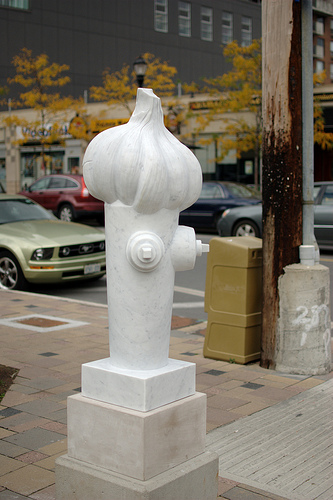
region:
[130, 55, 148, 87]
a black lamp post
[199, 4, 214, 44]
a window on a building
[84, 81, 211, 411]
a statue of a fire hydrant with a garlic head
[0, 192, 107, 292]
a Ford Mustang parked alongside the road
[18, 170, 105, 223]
a red car parked alongside the road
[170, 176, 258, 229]
a navy car parked alongside the road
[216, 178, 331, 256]
a grey car driving on a road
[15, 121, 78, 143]
a sign above a store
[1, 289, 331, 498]
a sidewalk next to a road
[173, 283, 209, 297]
a white stripe in a road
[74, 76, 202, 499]
white decorative statue placed on the sidewalk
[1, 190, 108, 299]
green Ford mustang parked in the street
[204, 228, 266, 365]
tan colored newspaper holder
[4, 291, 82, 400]
multi-colored brick sidewalk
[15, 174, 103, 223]
Four door maroon car parked in the street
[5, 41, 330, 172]
skinny trees with minimal yellow leaves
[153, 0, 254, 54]
row of windows on a multi-story building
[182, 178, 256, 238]
Navy blue vehicle parked in the street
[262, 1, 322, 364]
tall multi-hued brown telephone pole next to the sidewalk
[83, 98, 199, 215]
top shaped like onion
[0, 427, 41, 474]
bricks on the ground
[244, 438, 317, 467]
wood on the ground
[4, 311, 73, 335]
square on the ground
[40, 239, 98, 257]
front of mustang car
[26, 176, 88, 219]
side of the suv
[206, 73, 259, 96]
leaves of the tree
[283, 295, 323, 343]
graffiti on the pole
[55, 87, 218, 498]
White fire hydrant with garlic shaped top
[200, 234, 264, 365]
Golden mail vending machine in the background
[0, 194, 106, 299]
Golden Ford Mustang in the background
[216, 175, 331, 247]
Grey car driving by in the background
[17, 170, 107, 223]
Burgundy SUV parked in the background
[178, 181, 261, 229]
Blue sedan parked in the background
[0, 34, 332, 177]
Trees' leaves are turning yellow in the background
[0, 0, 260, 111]
Large grey building in the background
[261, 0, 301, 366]
Wooden mast next to the newspaper vending machine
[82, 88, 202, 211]
Garlic-shaped top of white fire hydrant statue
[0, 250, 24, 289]
wheel of a car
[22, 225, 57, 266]
light of a car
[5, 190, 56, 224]
windshield of a car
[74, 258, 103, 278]
license of a car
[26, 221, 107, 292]
bumper of a car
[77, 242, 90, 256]
brand of a car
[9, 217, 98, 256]
hood of a car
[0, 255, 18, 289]
rim of a car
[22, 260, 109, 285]
front bumper of a car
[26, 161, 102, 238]
car parked on a street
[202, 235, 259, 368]
A paper stand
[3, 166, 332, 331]
Vehicles on the road.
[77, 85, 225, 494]
a statue on the sidewalk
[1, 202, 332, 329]
The road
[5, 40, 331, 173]
Trees with yellow leaves.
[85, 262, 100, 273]
A license plate on the front of a car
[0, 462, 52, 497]
red brick in the side walk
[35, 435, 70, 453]
red brick in the side walk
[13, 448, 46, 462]
red brick in the side walk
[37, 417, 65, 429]
red brick in the side walk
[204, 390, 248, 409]
red brick in the side walk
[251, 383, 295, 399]
red brick in the side walk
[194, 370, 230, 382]
red brick in the side walk